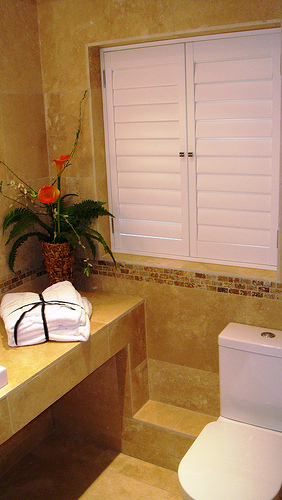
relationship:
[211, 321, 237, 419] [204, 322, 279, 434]
edge of tank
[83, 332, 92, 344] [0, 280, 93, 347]
part of towels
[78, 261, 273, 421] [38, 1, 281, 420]
side of wall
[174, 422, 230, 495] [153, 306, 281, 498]
part of toilet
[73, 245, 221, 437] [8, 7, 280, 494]
tiles of bathroom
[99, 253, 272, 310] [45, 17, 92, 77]
tiles on wall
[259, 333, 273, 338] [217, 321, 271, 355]
button on top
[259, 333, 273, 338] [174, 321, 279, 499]
button on toilet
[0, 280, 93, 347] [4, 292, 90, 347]
towels n black ribbon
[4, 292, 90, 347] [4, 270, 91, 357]
black ribbon tied around towels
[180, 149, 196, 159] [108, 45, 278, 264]
handles of shutters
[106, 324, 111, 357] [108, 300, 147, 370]
grout line between tile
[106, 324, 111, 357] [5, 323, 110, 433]
grout line between tile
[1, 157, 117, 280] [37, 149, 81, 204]
plant with flowers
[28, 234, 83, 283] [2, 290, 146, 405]
planter on counter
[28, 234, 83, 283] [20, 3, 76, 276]
planter in corner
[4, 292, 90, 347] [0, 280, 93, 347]
black ribbon of clothes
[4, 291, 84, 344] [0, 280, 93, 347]
black ribbon tied around towels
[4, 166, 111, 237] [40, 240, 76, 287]
flowers in planter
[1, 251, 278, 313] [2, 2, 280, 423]
mosaic on wall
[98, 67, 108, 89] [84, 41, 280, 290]
hinge on window